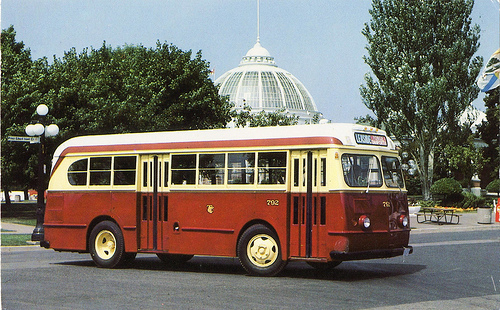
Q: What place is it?
A: It is a street.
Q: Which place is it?
A: It is a street.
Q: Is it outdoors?
A: Yes, it is outdoors.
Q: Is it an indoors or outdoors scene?
A: It is outdoors.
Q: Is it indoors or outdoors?
A: It is outdoors.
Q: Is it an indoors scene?
A: No, it is outdoors.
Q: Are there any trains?
A: No, there are no trains.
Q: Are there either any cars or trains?
A: No, there are no trains or cars.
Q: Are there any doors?
A: Yes, there is a door.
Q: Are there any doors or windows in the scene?
A: Yes, there is a door.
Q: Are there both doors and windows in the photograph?
A: Yes, there are both a door and a window.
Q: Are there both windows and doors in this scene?
A: Yes, there are both a door and a window.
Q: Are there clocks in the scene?
A: No, there are no clocks.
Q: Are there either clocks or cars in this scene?
A: No, there are no clocks or cars.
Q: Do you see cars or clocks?
A: No, there are no clocks or cars.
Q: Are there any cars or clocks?
A: No, there are no clocks or cars.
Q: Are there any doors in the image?
A: Yes, there is a door.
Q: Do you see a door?
A: Yes, there is a door.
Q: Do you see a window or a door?
A: Yes, there is a door.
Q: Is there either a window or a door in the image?
A: Yes, there is a door.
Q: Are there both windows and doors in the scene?
A: Yes, there are both a door and a window.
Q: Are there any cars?
A: No, there are no cars.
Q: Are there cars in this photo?
A: No, there are no cars.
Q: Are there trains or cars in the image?
A: No, there are no cars or trains.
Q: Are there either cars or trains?
A: No, there are no cars or trains.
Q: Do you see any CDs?
A: No, there are no cds.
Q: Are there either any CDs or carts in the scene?
A: No, there are no CDs or carts.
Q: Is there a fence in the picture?
A: No, there are no fences.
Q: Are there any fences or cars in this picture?
A: No, there are no fences or cars.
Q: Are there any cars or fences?
A: No, there are no fences or cars.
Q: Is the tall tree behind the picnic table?
A: Yes, the tree is behind the picnic table.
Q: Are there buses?
A: Yes, there is a bus.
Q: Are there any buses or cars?
A: Yes, there is a bus.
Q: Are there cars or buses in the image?
A: Yes, there is a bus.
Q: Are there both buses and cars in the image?
A: No, there is a bus but no cars.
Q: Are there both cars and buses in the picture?
A: No, there is a bus but no cars.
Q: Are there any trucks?
A: No, there are no trucks.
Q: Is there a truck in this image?
A: No, there are no trucks.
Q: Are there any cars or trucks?
A: No, there are no trucks or cars.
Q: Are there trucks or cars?
A: No, there are no trucks or cars.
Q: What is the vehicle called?
A: The vehicle is a bus.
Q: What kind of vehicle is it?
A: The vehicle is a bus.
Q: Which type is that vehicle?
A: This is a bus.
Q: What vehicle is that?
A: This is a bus.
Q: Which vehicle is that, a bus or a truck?
A: This is a bus.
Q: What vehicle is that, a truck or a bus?
A: This is a bus.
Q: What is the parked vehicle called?
A: The vehicle is a bus.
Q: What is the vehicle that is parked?
A: The vehicle is a bus.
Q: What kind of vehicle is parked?
A: The vehicle is a bus.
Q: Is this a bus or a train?
A: This is a bus.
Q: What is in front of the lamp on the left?
A: The bus is in front of the lamp.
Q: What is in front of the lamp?
A: The bus is in front of the lamp.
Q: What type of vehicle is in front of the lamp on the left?
A: The vehicle is a bus.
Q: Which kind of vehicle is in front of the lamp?
A: The vehicle is a bus.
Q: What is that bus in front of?
A: The bus is in front of the lamp.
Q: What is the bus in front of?
A: The bus is in front of the lamp.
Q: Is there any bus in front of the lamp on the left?
A: Yes, there is a bus in front of the lamp.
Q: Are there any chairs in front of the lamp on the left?
A: No, there is a bus in front of the lamp.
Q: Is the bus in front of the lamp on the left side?
A: Yes, the bus is in front of the lamp.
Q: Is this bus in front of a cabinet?
A: No, the bus is in front of the lamp.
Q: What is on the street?
A: The bus is on the street.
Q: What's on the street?
A: The bus is on the street.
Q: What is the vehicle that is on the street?
A: The vehicle is a bus.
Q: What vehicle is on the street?
A: The vehicle is a bus.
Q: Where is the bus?
A: The bus is on the street.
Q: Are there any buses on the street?
A: Yes, there is a bus on the street.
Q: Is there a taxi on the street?
A: No, there is a bus on the street.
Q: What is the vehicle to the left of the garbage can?
A: The vehicle is a bus.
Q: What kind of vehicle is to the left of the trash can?
A: The vehicle is a bus.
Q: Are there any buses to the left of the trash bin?
A: Yes, there is a bus to the left of the trash bin.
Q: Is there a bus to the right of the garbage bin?
A: No, the bus is to the left of the garbage bin.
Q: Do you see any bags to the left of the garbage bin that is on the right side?
A: No, there is a bus to the left of the trash bin.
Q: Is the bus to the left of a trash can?
A: Yes, the bus is to the left of a trash can.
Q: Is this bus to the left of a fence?
A: No, the bus is to the left of a trash can.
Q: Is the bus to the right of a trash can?
A: No, the bus is to the left of a trash can.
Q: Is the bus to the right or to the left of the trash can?
A: The bus is to the left of the trash can.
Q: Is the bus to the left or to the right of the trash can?
A: The bus is to the left of the trash can.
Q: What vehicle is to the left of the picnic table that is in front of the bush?
A: The vehicle is a bus.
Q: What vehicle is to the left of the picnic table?
A: The vehicle is a bus.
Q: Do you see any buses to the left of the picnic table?
A: Yes, there is a bus to the left of the picnic table.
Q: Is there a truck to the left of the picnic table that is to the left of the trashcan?
A: No, there is a bus to the left of the picnic table.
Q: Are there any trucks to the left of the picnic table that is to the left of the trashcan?
A: No, there is a bus to the left of the picnic table.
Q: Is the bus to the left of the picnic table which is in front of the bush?
A: Yes, the bus is to the left of the picnic table.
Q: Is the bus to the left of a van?
A: No, the bus is to the left of the picnic table.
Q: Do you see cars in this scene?
A: No, there are no cars.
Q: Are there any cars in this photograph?
A: No, there are no cars.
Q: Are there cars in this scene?
A: No, there are no cars.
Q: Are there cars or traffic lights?
A: No, there are no cars or traffic lights.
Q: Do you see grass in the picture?
A: Yes, there is grass.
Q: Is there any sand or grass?
A: Yes, there is grass.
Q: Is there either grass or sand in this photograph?
A: Yes, there is grass.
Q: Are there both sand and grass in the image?
A: No, there is grass but no sand.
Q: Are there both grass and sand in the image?
A: No, there is grass but no sand.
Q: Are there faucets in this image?
A: No, there are no faucets.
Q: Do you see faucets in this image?
A: No, there are no faucets.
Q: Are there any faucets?
A: No, there are no faucets.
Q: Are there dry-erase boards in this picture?
A: No, there are no dry-erase boards.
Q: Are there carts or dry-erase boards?
A: No, there are no dry-erase boards or carts.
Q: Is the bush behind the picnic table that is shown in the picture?
A: Yes, the bush is behind the picnic table.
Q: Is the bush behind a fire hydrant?
A: No, the bush is behind the picnic table.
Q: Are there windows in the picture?
A: Yes, there is a window.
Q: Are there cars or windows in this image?
A: Yes, there is a window.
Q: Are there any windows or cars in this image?
A: Yes, there is a window.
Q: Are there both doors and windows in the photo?
A: Yes, there are both a window and a door.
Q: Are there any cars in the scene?
A: No, there are no cars.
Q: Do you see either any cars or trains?
A: No, there are no cars or trains.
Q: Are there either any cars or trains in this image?
A: No, there are no cars or trains.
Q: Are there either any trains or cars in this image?
A: No, there are no cars or trains.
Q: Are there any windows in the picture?
A: Yes, there is a window.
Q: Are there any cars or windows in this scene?
A: Yes, there is a window.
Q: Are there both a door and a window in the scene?
A: Yes, there are both a window and a door.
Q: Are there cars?
A: No, there are no cars.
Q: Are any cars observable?
A: No, there are no cars.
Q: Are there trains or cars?
A: No, there are no cars or trains.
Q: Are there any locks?
A: No, there are no locks.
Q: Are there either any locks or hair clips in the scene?
A: No, there are no locks or hair clips.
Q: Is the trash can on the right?
A: Yes, the trash can is on the right of the image.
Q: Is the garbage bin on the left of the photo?
A: No, the garbage bin is on the right of the image.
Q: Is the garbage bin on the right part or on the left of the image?
A: The garbage bin is on the right of the image.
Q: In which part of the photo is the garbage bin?
A: The garbage bin is on the right of the image.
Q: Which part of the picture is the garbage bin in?
A: The garbage bin is on the right of the image.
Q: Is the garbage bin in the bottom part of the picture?
A: Yes, the garbage bin is in the bottom of the image.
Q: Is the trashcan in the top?
A: No, the trashcan is in the bottom of the image.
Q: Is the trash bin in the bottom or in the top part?
A: The trash bin is in the bottom of the image.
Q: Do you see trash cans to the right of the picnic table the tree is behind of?
A: Yes, there is a trash can to the right of the picnic table.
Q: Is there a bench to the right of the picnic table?
A: No, there is a trash can to the right of the picnic table.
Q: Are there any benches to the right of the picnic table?
A: No, there is a trash can to the right of the picnic table.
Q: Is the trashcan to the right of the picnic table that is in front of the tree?
A: Yes, the trashcan is to the right of the picnic table.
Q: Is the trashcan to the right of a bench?
A: No, the trashcan is to the right of the picnic table.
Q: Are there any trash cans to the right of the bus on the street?
A: Yes, there is a trash can to the right of the bus.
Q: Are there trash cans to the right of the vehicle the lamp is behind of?
A: Yes, there is a trash can to the right of the bus.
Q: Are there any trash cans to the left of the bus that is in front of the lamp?
A: No, the trash can is to the right of the bus.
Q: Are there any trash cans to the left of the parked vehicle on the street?
A: No, the trash can is to the right of the bus.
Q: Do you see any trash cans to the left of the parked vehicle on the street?
A: No, the trash can is to the right of the bus.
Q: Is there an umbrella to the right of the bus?
A: No, there is a trash can to the right of the bus.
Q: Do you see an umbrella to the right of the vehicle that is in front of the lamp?
A: No, there is a trash can to the right of the bus.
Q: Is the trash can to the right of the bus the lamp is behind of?
A: Yes, the trash can is to the right of the bus.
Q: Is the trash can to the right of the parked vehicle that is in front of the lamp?
A: Yes, the trash can is to the right of the bus.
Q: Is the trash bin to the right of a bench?
A: No, the trash bin is to the right of the bus.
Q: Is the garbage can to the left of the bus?
A: No, the garbage can is to the right of the bus.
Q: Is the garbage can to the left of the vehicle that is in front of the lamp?
A: No, the garbage can is to the right of the bus.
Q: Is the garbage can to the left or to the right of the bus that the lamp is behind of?
A: The garbage can is to the right of the bus.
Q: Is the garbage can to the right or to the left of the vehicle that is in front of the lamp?
A: The garbage can is to the right of the bus.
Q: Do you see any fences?
A: No, there are no fences.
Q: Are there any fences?
A: No, there are no fences.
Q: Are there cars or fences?
A: No, there are no fences or cars.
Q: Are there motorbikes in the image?
A: No, there are no motorbikes.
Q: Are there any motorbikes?
A: No, there are no motorbikes.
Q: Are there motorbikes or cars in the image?
A: No, there are no motorbikes or cars.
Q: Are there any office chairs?
A: No, there are no office chairs.